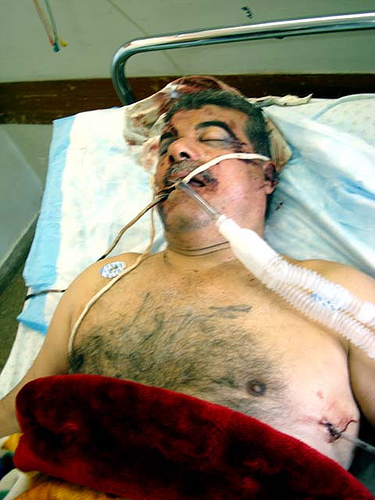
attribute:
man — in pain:
[1, 86, 372, 498]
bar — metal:
[97, 11, 373, 86]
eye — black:
[159, 141, 173, 154]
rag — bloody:
[117, 86, 227, 136]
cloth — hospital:
[39, 106, 125, 261]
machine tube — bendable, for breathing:
[174, 174, 212, 226]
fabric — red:
[6, 371, 373, 499]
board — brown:
[0, 72, 371, 127]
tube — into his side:
[183, 164, 352, 347]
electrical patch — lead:
[72, 240, 121, 296]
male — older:
[126, 87, 373, 425]